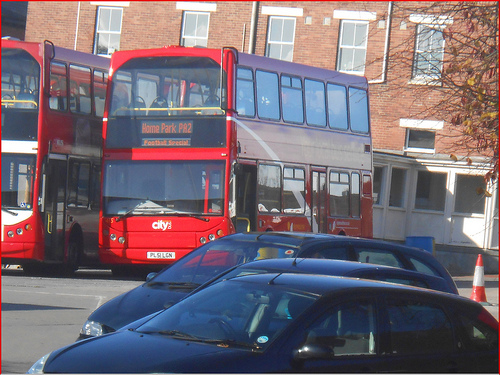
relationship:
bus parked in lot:
[93, 46, 372, 280] [5, 236, 495, 364]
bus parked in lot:
[0, 16, 110, 281] [0, 265, 496, 373]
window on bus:
[232, 62, 257, 117] [93, 46, 372, 280]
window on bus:
[258, 71, 280, 118] [93, 46, 372, 280]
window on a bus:
[278, 70, 305, 132] [96, 31, 241, 258]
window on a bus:
[109, 66, 216, 106] [99, 41, 391, 255]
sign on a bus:
[135, 119, 195, 150] [93, 46, 372, 280]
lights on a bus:
[98, 227, 133, 250] [103, 40, 318, 269]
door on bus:
[42, 149, 72, 271] [0, 16, 110, 281]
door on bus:
[234, 148, 263, 237] [93, 46, 372, 280]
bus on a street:
[99, 48, 390, 241] [8, 235, 498, 324]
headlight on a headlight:
[102, 224, 127, 250] [199, 226, 221, 246]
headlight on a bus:
[102, 224, 127, 250] [93, 46, 372, 280]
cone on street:
[469, 247, 491, 307] [0, 263, 130, 365]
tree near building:
[365, 3, 496, 200] [21, 0, 499, 276]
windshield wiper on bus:
[114, 199, 225, 226] [93, 46, 372, 280]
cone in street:
[469, 252, 492, 307] [12, 273, 81, 321]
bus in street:
[93, 46, 372, 280] [14, 277, 91, 316]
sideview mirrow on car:
[294, 338, 329, 362] [31, 257, 484, 372]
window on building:
[402, 109, 468, 163] [139, 12, 499, 305]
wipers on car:
[140, 318, 277, 358] [27, 269, 494, 372]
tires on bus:
[55, 219, 99, 269] [0, 29, 107, 274]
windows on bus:
[237, 62, 368, 142] [2, 31, 102, 300]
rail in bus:
[113, 96, 223, 118] [93, 46, 372, 280]